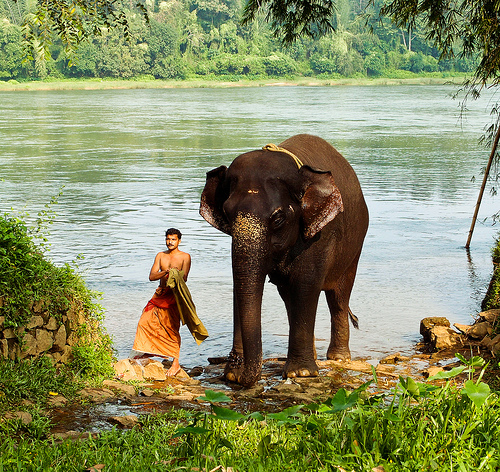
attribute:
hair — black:
[163, 226, 183, 238]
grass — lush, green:
[9, 379, 497, 469]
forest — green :
[2, 1, 499, 98]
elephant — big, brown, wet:
[196, 131, 361, 380]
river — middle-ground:
[2, 92, 493, 351]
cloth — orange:
[132, 289, 189, 359]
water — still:
[4, 89, 498, 359]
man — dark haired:
[132, 227, 191, 375]